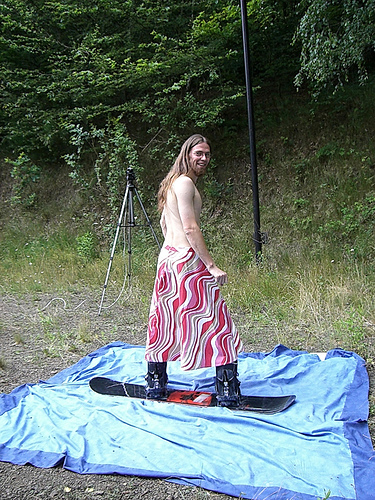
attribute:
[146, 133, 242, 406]
man — shirtless, bare chested, standing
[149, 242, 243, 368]
skirt — colorful, red, pink, grey, white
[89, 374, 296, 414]
snowboard — black, red, orange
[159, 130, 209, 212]
hair — long, brown, blond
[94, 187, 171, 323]
tripod — set up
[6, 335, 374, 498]
tarp — blue, two tone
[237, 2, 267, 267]
pole — black, steel, large, painted black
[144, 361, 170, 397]
snowboard boot — black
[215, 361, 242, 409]
snowboard boot — black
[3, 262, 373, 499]
ground — sandy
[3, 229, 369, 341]
grass — tall, tan, green